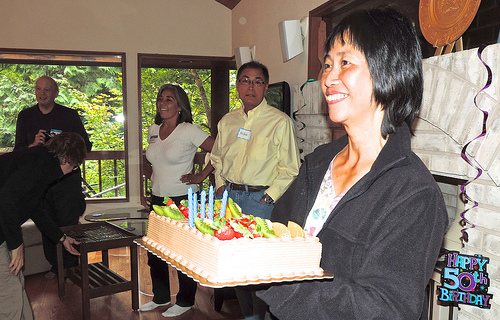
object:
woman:
[209, 5, 449, 320]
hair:
[321, 12, 431, 141]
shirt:
[207, 96, 305, 206]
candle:
[191, 190, 200, 223]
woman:
[137, 80, 208, 319]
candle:
[207, 181, 218, 226]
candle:
[218, 188, 230, 226]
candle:
[192, 188, 199, 223]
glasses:
[238, 76, 272, 90]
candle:
[192, 185, 196, 225]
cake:
[142, 185, 325, 281]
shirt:
[147, 120, 209, 198]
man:
[207, 60, 302, 318]